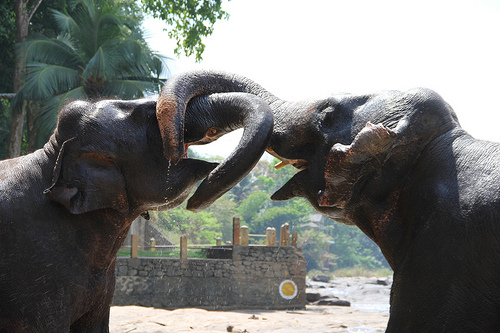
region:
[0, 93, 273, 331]
large wet gray elephant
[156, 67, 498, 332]
large wet gray elephant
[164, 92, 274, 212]
large wet gray elephant trunk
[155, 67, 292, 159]
large wet gray elephant trunk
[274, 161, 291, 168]
short yellow elephant tusk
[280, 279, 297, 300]
painted yellow and white circle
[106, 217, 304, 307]
gray stone wall with wooden posts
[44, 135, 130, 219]
large wet gray elephant ear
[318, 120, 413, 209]
large wet gray elephant ear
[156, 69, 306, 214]
two large wet gray elephant trunks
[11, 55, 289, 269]
the head of a elephant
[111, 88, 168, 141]
the eye of a elephant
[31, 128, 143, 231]
the ear of a elephant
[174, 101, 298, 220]
the trunk of a elephant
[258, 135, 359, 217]
the mouth of a elephant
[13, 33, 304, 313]
the body of a elephant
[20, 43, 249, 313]
the big grey head of a elephant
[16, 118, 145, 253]
the big grey ear of a elephant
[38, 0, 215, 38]
green leaves on a tree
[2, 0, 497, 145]
green trees on side of clear bright sky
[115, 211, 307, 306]
wooden poles on top of stone wall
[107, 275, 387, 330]
tan ground with rocks and bumpy areas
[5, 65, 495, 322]
dark gray elephants facing each other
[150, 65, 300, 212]
curled trunk over another elephant's curled trunk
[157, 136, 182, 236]
water dripping from trunk end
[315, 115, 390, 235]
ruffled ear curled over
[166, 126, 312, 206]
open mouths on both elephants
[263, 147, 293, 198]
blunt tusk through angled mouth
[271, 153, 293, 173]
a tiny elephant tusk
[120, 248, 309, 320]
grey stone retaining wall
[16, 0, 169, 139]
fronds of a palm tree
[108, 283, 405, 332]
ground is sandy with stones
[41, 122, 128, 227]
tip of ear is curled up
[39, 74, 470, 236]
elephants tangle trunks